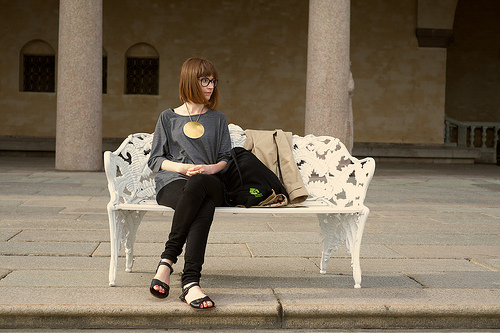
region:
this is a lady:
[163, 66, 221, 315]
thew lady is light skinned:
[161, 158, 187, 171]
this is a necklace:
[187, 104, 199, 128]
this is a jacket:
[257, 130, 289, 158]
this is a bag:
[231, 149, 261, 201]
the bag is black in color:
[244, 157, 261, 180]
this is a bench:
[311, 141, 358, 263]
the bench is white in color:
[323, 147, 346, 213]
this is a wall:
[224, 11, 266, 78]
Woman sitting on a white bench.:
[24, 12, 466, 317]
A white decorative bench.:
[101, 110, 384, 297]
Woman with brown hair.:
[166, 50, 231, 133]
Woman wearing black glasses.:
[172, 42, 227, 137]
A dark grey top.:
[148, 98, 229, 188]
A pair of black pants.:
[140, 182, 220, 282]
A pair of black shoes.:
[138, 255, 218, 316]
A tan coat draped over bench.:
[244, 120, 313, 208]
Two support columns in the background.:
[40, 4, 389, 188]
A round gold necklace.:
[164, 50, 224, 158]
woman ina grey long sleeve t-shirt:
[148, 57, 233, 308]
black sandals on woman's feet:
[150, 260, 215, 308]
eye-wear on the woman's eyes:
[197, 75, 220, 88]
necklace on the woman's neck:
[183, 102, 204, 122]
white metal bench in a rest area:
[102, 122, 376, 289]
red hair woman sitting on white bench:
[101, 55, 376, 310]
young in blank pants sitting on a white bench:
[102, 54, 375, 310]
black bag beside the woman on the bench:
[225, 145, 287, 205]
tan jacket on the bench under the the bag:
[242, 129, 308, 206]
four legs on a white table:
[107, 211, 370, 288]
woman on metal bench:
[142, 55, 232, 316]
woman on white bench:
[100, 45, 377, 319]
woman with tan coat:
[140, 57, 316, 313]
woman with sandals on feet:
[133, 54, 233, 315]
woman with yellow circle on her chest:
[145, 64, 235, 316]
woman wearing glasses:
[138, 52, 227, 316]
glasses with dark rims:
[185, 75, 222, 90]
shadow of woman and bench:
[211, 261, 490, 308]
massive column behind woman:
[47, 2, 113, 177]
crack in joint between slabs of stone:
[265, 273, 287, 325]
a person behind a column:
[337, 57, 361, 155]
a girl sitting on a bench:
[143, 42, 225, 313]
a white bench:
[97, 117, 374, 296]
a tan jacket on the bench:
[240, 128, 307, 204]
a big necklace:
[178, 93, 205, 138]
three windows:
[15, 29, 165, 103]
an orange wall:
[0, 1, 447, 151]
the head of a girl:
[171, 46, 224, 112]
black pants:
[155, 168, 217, 278]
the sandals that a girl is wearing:
[152, 251, 214, 311]